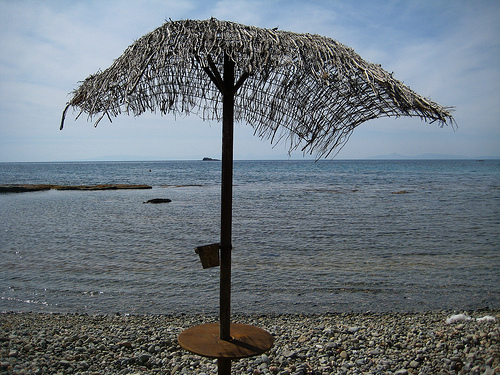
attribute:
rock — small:
[406, 358, 421, 369]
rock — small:
[140, 350, 148, 364]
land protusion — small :
[3, 174, 150, 198]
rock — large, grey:
[279, 349, 296, 359]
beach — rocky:
[5, 309, 498, 368]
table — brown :
[177, 322, 274, 359]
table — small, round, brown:
[176, 323, 276, 370]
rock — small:
[6, 343, 17, 360]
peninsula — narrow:
[49, 175, 105, 205]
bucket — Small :
[197, 241, 219, 268]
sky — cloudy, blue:
[387, 10, 484, 71]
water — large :
[3, 162, 499, 316]